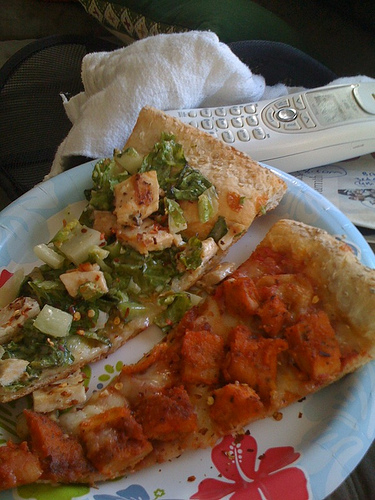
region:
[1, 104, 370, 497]
two slices of pizza on a colorful disposable plate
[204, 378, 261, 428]
red buffalo chicken pizza topping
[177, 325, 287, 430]
three buffalo chicken pieces on a slice of pizza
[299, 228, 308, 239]
sesame seed on a pizza crust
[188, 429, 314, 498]
red floral design on a disposable plate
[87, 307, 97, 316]
red pepper seed on a slice of pizza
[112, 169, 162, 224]
grilled chicken toppin on a slice of pizza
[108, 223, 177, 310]
chicken piece and green vegetable pizza topping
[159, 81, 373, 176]
white cordless phone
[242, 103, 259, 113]
button on a cordless phone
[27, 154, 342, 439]
Pizza is on the plate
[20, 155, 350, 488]
A plate is beneath the pizza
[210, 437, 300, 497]
A red flower is drawn on the plate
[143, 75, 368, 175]
A phone is visible behind the plate of pizza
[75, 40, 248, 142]
A white cloth is near the phone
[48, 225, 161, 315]
Vegetables are on the left slice of pizza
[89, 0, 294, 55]
A pillow is visible in the background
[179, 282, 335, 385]
Meat is on the rightmost piece of pizza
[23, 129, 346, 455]
Two pieces of pizza sit atop the plate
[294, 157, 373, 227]
Papers beneath the phone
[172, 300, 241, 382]
a slice of pizza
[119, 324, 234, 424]
a slice of pizza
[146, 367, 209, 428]
a slice of pizza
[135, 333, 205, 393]
a slice of pizza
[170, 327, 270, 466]
a slice of pizza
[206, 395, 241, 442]
a slice of pizza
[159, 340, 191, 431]
a slice of pizza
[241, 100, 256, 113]
a button on the phone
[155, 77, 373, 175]
a white cordless phone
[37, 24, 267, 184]
a white towel under the phone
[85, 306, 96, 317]
a yellow pepper flake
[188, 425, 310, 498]
a red flower pattern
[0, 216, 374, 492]
a slice of pizza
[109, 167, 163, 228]
a piece of chicken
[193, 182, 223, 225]
a green leaf of lettuce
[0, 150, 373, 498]
a paper plate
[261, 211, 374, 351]
the crust of the pizza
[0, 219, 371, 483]
a small slice of pizza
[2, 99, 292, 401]
a small slice of pizza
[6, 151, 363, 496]
a blue flowered paper plate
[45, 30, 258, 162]
a white fabric towel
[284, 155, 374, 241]
a folded newspaper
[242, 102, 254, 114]
phone button number 1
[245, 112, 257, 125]
phone button number 2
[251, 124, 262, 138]
phone button number 3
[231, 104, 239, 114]
phone button number 4